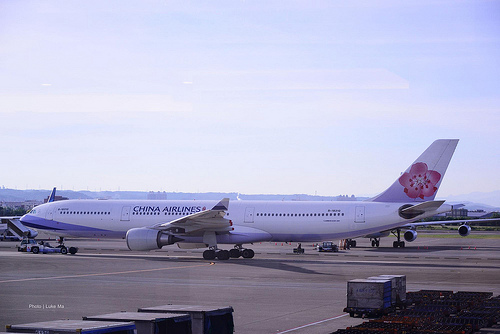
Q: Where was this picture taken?
A: Airport.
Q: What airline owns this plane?
A: China Airlines.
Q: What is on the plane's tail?
A: Flower.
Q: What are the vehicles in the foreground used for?
A: Transporting luggage.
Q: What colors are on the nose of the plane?
A: Blue.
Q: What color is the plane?
A: White.